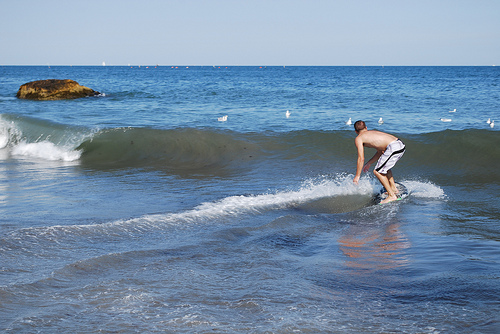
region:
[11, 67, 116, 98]
Brown rock above sea waves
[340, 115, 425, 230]
Surfer without any shirt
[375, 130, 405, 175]
White shorts on man with black stripes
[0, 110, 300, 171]
Incoming wave near surfer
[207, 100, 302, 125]
Seagulls out at sea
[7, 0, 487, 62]
Light blue clear horizon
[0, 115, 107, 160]
Wave slamming against the water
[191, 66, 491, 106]
Dark blue clear ocean water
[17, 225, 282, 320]
Foamy and motionless water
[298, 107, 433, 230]
Surfer riding towards a sea wave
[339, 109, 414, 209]
man surfing in the ocean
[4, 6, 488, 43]
blue sky in the background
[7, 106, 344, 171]
wave rolling in from the ocean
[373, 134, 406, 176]
swim trunks of a surfer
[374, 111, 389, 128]
white bird on the water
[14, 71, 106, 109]
rock in the ocean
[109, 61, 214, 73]
boats in the distance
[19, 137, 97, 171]
white crashing water from a wave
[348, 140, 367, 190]
left arm of a surfer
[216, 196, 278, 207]
white foam from the ocean water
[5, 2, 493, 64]
The sky is blue.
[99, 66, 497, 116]
the water is blue.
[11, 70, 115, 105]
Rock in the ocean.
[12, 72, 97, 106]
the rock is brown.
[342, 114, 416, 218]
The surfer is male.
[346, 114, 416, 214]
The man is standing on a surf board.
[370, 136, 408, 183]
The man's shorts are grey and black.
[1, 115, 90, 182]
The waves are white.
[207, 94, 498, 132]
Birds in the ocean.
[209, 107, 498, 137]
The birds are white.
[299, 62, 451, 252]
a person surfing in the water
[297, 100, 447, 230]
a person surfing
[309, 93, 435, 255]
a man surfing in the water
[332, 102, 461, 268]
a man surfing during the day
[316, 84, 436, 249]
a man leaning forward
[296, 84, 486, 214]
a man leaning forward on a surfboard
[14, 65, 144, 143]
a large rock in the water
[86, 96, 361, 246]
a small wave in the water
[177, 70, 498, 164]
white birds sitting on the water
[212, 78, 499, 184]
birds sitting in the water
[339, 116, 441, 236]
The man is surfing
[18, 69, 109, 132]
There is a brown rock in the water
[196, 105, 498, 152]
There are white birds in the water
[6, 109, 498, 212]
There is a waving coming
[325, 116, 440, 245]
There is a man on a surfboard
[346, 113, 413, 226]
The man is wearing white swim trunks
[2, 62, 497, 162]
The water is blue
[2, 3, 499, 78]
The sky is clear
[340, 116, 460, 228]
His swim trunks have a black stripe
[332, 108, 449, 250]
The surfer is getting ready for the wave